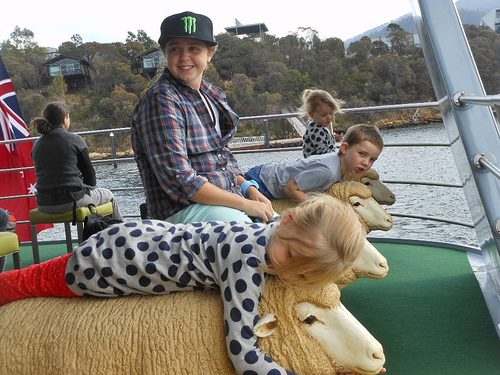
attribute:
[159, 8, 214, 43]
baseball cap — black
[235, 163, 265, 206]
watch — blue 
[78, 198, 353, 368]
shirt — polka dotted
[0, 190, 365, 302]
knit pants — red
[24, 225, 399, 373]
sheep — plastic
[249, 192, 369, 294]
hair — blonde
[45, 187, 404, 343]
girl — young blond 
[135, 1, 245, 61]
ball cap — black ball 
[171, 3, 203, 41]
green logo — green 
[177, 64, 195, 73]
smile — big 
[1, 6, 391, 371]
kids — Some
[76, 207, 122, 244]
backpack — black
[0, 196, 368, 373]
child — small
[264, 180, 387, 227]
statue — animal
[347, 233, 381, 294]
statue — animal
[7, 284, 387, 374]
statue — animal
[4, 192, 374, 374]
girl — little, blonde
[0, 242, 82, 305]
pants — red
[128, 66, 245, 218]
shirt — long sleeve, button up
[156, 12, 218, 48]
cap — baseball cap, monster brand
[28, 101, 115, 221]
woman/bench — dark haired 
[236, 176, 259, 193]
blue band — wide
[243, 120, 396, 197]
boy — young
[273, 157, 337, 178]
t-shirt —  gray 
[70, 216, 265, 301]
shirt —  polka dot 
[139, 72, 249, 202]
shirt — dark plaid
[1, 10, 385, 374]
family —  taking a trip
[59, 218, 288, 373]
shirt — polka dot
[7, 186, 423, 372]
child — young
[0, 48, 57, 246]
flag — blue hanging  , red, white,  , blue, white , red 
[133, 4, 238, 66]
ballcap — black 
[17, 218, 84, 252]
bench — small 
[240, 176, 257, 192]
wristband — blue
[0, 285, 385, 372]
sheep — plastic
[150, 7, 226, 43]
cap — black,  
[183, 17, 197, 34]
logo —  green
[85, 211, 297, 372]
top — black polka  , white   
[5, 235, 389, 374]
sheep — fake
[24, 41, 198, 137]
hillside — wooded